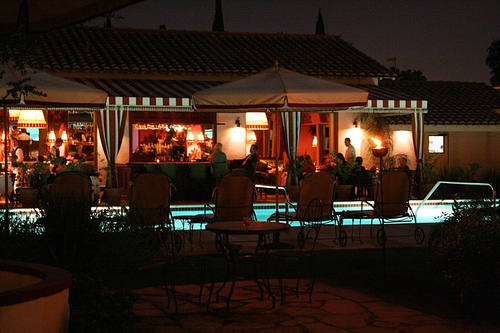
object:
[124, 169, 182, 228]
chair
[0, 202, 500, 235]
pool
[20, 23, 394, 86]
roof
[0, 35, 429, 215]
building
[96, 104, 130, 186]
curtain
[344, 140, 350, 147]
face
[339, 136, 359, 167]
man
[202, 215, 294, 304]
table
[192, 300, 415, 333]
shadow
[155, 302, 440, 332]
ground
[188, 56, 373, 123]
umbrella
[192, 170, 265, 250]
chair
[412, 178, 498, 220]
rail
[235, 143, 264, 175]
person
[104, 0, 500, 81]
sky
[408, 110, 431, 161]
curtain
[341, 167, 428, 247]
chair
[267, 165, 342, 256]
chair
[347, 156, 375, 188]
person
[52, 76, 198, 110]
tent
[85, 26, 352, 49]
top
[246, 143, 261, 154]
head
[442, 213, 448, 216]
leaf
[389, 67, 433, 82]
tree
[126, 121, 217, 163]
bar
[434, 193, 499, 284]
bush